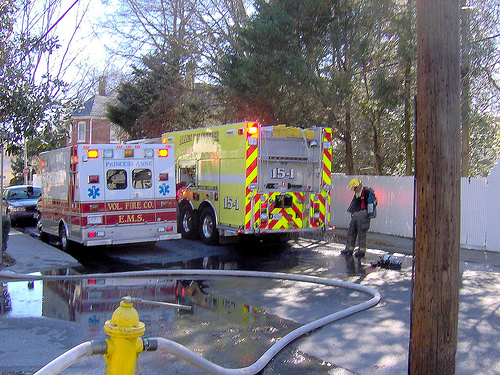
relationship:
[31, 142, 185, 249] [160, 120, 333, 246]
ambulance parked next to fire truck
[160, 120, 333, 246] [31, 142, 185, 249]
fire truck parked next to ambulance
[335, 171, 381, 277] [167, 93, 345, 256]
firefighter waiting behind fire truck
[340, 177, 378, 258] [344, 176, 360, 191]
firefighter wearing helmet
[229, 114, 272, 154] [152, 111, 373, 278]
light on truck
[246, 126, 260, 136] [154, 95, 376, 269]
light on truck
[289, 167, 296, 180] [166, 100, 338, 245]
number one on truck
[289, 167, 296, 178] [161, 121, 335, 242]
number one on truck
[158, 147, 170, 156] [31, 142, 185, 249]
light on ambulance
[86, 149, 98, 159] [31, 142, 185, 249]
light on ambulance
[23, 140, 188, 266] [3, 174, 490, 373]
ambulance on street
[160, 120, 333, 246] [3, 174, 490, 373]
fire truck on street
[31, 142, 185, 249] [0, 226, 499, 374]
ambulance on road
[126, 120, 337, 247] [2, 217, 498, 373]
fire truck on street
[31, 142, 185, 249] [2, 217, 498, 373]
ambulance on street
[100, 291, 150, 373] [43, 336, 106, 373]
hydrant with fire hose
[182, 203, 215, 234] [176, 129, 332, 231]
wheels on fire truck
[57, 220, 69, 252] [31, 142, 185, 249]
wheel on ambulance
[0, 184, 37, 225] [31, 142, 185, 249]
car near ambulance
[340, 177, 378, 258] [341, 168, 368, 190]
firefighter with helmet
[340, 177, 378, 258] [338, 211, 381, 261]
firefighter without gear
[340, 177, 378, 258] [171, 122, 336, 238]
firefighter by fire truck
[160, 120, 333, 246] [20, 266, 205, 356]
fire truck by road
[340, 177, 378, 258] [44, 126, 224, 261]
firefighter by ambulence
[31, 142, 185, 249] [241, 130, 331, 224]
ambulance with fire truck